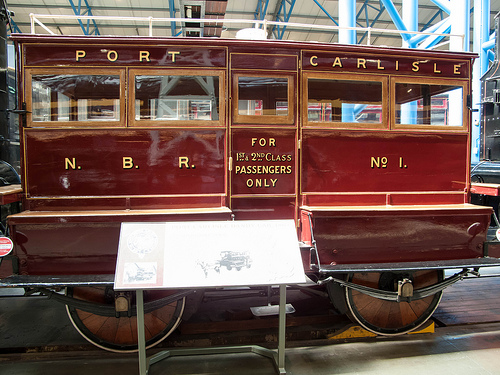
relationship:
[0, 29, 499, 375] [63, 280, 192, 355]
antique trolley has trolley wheel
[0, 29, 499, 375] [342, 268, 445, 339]
antique trolley has wheel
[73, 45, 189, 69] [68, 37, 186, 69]
text says port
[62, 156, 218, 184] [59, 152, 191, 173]
text says n.b.r.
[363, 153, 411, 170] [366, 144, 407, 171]
text says no 1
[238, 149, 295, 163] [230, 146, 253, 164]
text says 1st class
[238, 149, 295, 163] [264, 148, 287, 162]
text says 2nd class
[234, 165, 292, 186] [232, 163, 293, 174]
text spelling passengers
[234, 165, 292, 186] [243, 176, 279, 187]
text spelling only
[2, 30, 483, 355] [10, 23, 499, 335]
train displayed in museum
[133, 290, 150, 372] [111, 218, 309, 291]
leg supporting information sign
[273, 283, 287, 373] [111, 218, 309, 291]
leg supporting information sign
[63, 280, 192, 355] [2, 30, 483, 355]
trolley wheel mounted on train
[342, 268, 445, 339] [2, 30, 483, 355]
wheel mounted on train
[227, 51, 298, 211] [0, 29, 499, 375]
door leading to antique trolley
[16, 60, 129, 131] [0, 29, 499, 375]
windows built into antique trolley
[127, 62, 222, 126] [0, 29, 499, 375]
windows built into antique trolley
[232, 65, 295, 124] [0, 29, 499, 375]
windows built into antique trolley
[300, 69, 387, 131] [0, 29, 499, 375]
windows built into antique trolley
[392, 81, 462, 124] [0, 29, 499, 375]
window built into antique trolley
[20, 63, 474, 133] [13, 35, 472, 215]
trim lining car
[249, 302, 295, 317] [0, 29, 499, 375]
step leading to antique trolley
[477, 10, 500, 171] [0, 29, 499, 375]
black train standing next to antique trolley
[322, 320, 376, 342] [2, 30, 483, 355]
block securing train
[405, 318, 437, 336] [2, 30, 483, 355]
block securing train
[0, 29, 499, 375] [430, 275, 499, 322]
antique trolley standing on floor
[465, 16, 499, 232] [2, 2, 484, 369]
train displayed in museum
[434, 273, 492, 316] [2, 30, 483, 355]
wooden hub mounted on train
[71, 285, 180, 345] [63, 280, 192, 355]
hub holding trolley wheel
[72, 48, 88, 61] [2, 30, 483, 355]
letter painted on train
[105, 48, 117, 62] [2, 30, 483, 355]
letter painted on train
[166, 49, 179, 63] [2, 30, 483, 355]
letter painted on train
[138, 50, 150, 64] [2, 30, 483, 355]
letter painted on train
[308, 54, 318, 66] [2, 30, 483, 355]
letter painted on train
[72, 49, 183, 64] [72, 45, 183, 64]
lettering spelling port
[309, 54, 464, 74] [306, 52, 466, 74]
lettering spelling carlisle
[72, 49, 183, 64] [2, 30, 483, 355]
lettering painted on train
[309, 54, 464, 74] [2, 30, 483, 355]
lettering painted on train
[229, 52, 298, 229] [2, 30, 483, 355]
train door leading to train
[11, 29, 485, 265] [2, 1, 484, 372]
antique trolley displayed in museum exhibit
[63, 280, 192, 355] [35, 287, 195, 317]
trolley wheel mounted on brace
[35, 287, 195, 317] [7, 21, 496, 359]
brace mounted on trolley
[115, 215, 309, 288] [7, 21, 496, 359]
information sign explaining trolley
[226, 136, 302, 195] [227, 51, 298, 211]
sign on door displayed on door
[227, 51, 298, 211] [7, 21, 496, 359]
door leading to trolley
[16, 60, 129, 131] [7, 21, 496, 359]
windows are on trolley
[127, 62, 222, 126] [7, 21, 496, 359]
windows are on trolley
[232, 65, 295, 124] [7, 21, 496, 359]
windows are on trolley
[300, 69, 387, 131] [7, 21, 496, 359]
windows are on trolley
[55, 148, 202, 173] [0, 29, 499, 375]
n.b.r on side of antique trolley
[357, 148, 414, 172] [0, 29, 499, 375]
no 1 on side of antique trolley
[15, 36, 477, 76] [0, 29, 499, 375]
port carlisle on top of antique trolley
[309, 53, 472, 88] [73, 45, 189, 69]
text carlisle text